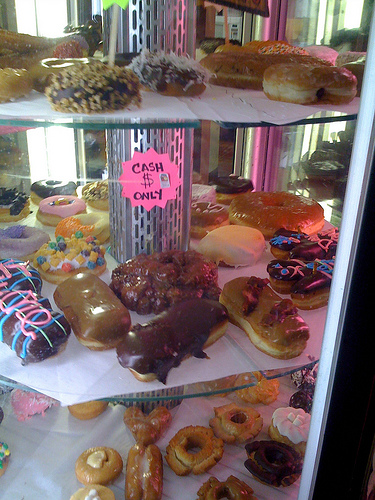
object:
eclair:
[115, 297, 228, 385]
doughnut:
[35, 194, 86, 226]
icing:
[39, 194, 87, 218]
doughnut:
[125, 46, 217, 97]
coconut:
[125, 52, 217, 92]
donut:
[75, 445, 123, 486]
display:
[0, 0, 375, 499]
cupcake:
[269, 227, 309, 260]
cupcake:
[266, 259, 307, 294]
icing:
[270, 231, 301, 245]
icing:
[286, 265, 304, 279]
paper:
[0, 375, 305, 500]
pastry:
[123, 406, 172, 447]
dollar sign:
[141, 173, 155, 189]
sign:
[118, 147, 183, 211]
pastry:
[194, 224, 266, 268]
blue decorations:
[282, 268, 287, 274]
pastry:
[0, 258, 71, 366]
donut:
[209, 401, 264, 444]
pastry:
[75, 446, 123, 486]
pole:
[309, 0, 374, 423]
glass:
[2, 0, 375, 403]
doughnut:
[44, 60, 142, 115]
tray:
[0, 46, 359, 131]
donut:
[53, 272, 131, 350]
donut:
[219, 275, 311, 360]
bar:
[219, 273, 311, 359]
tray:
[0, 184, 328, 400]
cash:
[131, 162, 164, 175]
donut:
[33, 230, 107, 286]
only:
[133, 189, 162, 201]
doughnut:
[70, 484, 115, 499]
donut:
[267, 407, 310, 458]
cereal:
[33, 231, 106, 273]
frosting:
[271, 269, 280, 278]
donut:
[164, 424, 223, 476]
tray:
[0, 370, 318, 500]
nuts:
[62, 75, 92, 110]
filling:
[86, 450, 107, 468]